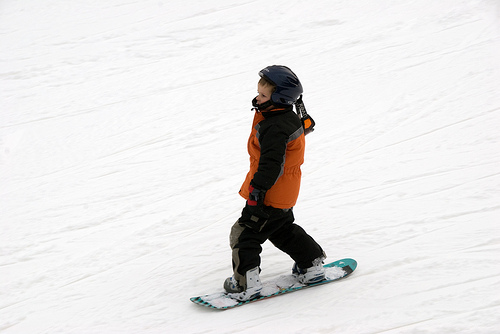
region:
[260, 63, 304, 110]
black helmet child is wearing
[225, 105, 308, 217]
orange and black coat child is wearing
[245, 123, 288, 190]
black sleeve of coat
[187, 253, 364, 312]
snowboard child is riding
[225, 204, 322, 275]
black pants child is wearing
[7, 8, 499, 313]
mountain child is snowboarding down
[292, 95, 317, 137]
snow goggles hanging off black helmet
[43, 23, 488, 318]
tracks in the snow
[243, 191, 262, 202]
black glove child is wearing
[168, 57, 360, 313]
child snowboarding down a mountain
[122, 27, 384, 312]
a young child snowboards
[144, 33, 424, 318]
the boy is snowboarding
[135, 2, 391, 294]
the boy has a helmet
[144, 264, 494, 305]
the snowboard is blue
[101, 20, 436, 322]
the season is winter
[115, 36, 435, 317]
snowboarding for young children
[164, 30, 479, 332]
the helmet is black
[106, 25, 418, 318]
the jacket is orange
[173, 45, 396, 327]
the boots are clipped in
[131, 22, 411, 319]
the gloves are black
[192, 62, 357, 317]
Boy riding snowboard on slope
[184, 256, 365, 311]
Snowboard on ski slope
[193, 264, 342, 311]
Snow on top of snowboard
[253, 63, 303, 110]
Helmet on boy's head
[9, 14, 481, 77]
Ski tracks on slope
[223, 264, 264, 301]
Boot clamp on snowboard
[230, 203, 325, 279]
Snow pants on boy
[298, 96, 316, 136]
Ski goggles hanging from helmet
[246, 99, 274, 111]
Chin strap of helmet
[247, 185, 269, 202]
Winter gloves on boy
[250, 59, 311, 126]
the head of a boy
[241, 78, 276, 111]
the eye of a boy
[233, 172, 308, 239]
the hand of a boy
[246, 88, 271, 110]
the nose of a boy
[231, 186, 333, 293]
the legs of a boy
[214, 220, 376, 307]
the feet of a boy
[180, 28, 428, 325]
a boy in the snow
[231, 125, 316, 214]
the arm of a boy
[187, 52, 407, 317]
a helmet of a boy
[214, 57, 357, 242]
a boy wearing a coat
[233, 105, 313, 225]
Wearing an orange coat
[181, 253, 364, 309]
White and blue board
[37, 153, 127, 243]
The snow is white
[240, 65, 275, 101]
White boy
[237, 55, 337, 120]
Helmet is black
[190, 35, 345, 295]
This is a young boy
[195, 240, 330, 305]
Shoes in the board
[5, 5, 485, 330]
Daytime is the time of day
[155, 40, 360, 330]
Only person in the shot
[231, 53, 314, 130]
Looking ahead